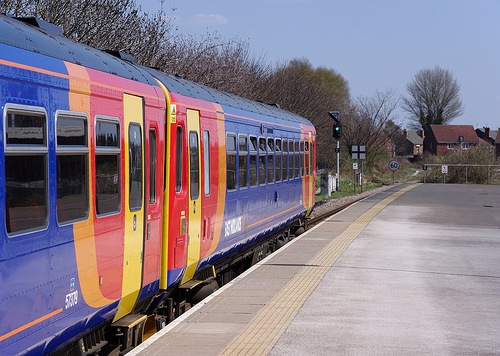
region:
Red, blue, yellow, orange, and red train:
[2, 25, 330, 355]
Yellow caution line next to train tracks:
[212, 166, 423, 354]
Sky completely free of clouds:
[95, 0, 499, 131]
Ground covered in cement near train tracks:
[97, 149, 495, 350]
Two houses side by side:
[389, 107, 494, 184]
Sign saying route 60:
[379, 154, 404, 179]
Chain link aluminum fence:
[413, 153, 498, 183]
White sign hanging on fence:
[436, 158, 454, 183]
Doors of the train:
[113, 91, 160, 302]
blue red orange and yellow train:
[14, 48, 318, 266]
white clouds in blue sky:
[192, 3, 243, 37]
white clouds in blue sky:
[250, 15, 287, 60]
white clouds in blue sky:
[288, 5, 379, 46]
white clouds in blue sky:
[358, 37, 375, 79]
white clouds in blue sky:
[438, 12, 492, 52]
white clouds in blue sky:
[450, 48, 492, 87]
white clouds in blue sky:
[355, 36, 397, 103]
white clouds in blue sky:
[247, 8, 304, 33]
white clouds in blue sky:
[306, 1, 350, 39]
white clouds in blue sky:
[215, 6, 284, 47]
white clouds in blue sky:
[353, 4, 398, 70]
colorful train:
[1, 53, 341, 263]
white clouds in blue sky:
[355, 13, 385, 33]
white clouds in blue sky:
[360, 22, 388, 50]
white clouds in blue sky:
[422, 21, 457, 53]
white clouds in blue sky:
[361, 18, 408, 58]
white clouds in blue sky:
[272, 18, 400, 50]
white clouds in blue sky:
[252, 26, 319, 53]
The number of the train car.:
[65, 290, 79, 309]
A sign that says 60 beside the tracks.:
[387, 159, 399, 184]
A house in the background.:
[397, 127, 425, 156]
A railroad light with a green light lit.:
[331, 111, 343, 188]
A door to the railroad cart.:
[112, 95, 144, 322]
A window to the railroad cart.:
[225, 132, 238, 192]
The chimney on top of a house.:
[402, 127, 408, 136]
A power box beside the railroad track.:
[321, 170, 337, 195]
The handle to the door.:
[146, 220, 151, 240]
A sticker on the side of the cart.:
[171, 104, 176, 122]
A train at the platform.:
[0, 15, 330, 340]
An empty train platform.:
[237, 179, 497, 351]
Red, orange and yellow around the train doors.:
[61, 63, 233, 310]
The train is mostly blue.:
[6, 33, 327, 333]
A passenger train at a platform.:
[13, 29, 330, 347]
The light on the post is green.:
[326, 109, 347, 185]